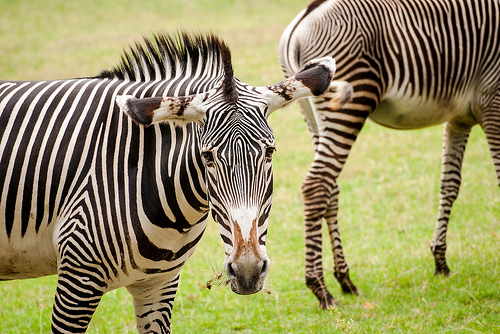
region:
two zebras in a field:
[2, 0, 498, 327]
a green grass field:
[4, 2, 498, 331]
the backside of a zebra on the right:
[282, 8, 498, 305]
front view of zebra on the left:
[0, 34, 333, 319]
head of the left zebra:
[115, 52, 335, 293]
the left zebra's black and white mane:
[95, 37, 234, 99]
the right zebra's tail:
[283, 42, 353, 105]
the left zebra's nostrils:
[228, 262, 268, 276]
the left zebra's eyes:
[200, 147, 273, 162]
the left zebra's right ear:
[112, 93, 207, 123]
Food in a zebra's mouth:
[204, 267, 284, 297]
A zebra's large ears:
[111, 57, 333, 117]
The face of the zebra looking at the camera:
[122, 52, 337, 294]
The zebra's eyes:
[196, 144, 280, 162]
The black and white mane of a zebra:
[107, 33, 235, 102]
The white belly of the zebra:
[0, 225, 62, 283]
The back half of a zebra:
[280, 0, 498, 295]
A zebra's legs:
[300, 108, 462, 297]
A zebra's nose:
[221, 254, 270, 282]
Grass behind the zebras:
[0, 2, 497, 332]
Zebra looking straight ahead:
[131, 75, 356, 290]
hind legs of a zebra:
[292, 25, 382, 295]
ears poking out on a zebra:
[106, 95, 223, 135]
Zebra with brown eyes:
[198, 144, 223, 166]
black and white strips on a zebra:
[336, 8, 463, 88]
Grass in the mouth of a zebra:
[206, 258, 234, 290]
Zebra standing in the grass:
[299, 170, 469, 307]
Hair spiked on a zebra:
[86, 33, 260, 104]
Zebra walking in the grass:
[292, 238, 367, 323]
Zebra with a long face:
[203, 151, 284, 288]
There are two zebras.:
[8, 0, 497, 323]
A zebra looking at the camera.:
[171, 83, 296, 314]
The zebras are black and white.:
[12, 0, 498, 332]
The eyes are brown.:
[187, 134, 282, 169]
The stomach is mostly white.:
[387, 99, 460, 131]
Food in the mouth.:
[196, 262, 281, 303]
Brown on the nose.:
[226, 217, 266, 259]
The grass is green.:
[202, 169, 497, 331]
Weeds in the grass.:
[297, 264, 387, 317]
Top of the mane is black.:
[106, 39, 242, 93]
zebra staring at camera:
[12, 33, 284, 333]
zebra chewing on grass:
[34, 42, 276, 332]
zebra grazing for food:
[7, 32, 295, 327]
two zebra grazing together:
[21, 11, 478, 332]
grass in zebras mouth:
[196, 267, 306, 309]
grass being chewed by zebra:
[198, 248, 288, 308]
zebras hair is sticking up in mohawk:
[56, 17, 253, 121]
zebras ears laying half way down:
[109, 61, 350, 135]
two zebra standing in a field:
[11, 23, 491, 304]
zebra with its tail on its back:
[248, 12, 410, 125]